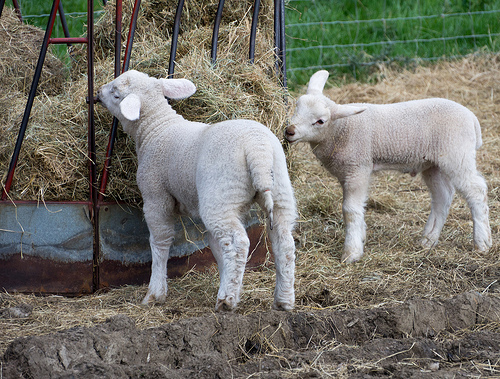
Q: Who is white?
A: Sheep.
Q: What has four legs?
A: One sheep.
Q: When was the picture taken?
A: Daytime.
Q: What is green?
A: Grass.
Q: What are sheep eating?
A: Hay.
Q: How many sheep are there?
A: Two.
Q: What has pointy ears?
A: The sheep.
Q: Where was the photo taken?
A: At the farm.